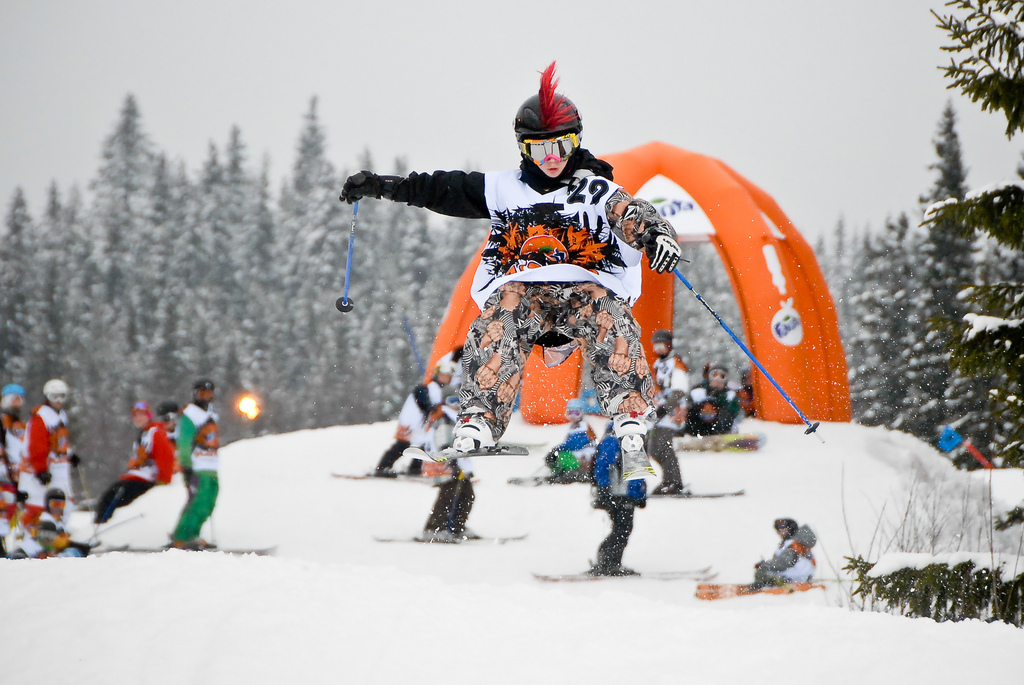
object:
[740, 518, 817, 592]
person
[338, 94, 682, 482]
boy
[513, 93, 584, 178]
head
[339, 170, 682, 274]
arms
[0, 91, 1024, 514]
snow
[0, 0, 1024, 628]
trees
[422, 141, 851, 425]
dome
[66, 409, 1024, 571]
slope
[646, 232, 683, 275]
hand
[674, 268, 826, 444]
pole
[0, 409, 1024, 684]
ground surface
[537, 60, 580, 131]
helmet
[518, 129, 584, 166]
goggles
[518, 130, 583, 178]
skier's face